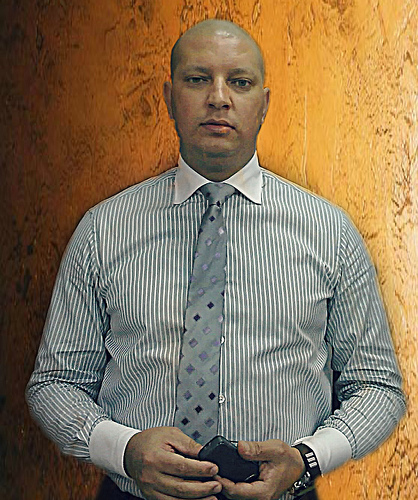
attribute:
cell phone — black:
[193, 424, 261, 482]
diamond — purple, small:
[203, 237, 216, 250]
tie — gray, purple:
[171, 182, 237, 445]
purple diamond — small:
[203, 235, 213, 246]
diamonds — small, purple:
[210, 275, 217, 283]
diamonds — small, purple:
[202, 326, 209, 331]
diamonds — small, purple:
[192, 314, 199, 319]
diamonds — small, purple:
[216, 226, 223, 233]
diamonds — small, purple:
[196, 376, 204, 386]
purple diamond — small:
[217, 222, 223, 236]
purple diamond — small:
[200, 238, 213, 248]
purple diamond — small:
[201, 324, 209, 333]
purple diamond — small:
[188, 336, 201, 349]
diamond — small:
[193, 248, 198, 258]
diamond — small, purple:
[196, 373, 206, 389]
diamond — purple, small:
[193, 312, 204, 324]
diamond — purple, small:
[184, 334, 200, 351]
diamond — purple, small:
[199, 324, 213, 338]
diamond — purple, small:
[192, 375, 208, 387]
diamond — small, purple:
[200, 323, 215, 338]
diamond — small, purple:
[182, 362, 197, 376]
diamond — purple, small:
[208, 361, 220, 376]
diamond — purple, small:
[196, 349, 210, 364]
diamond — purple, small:
[183, 361, 195, 376]